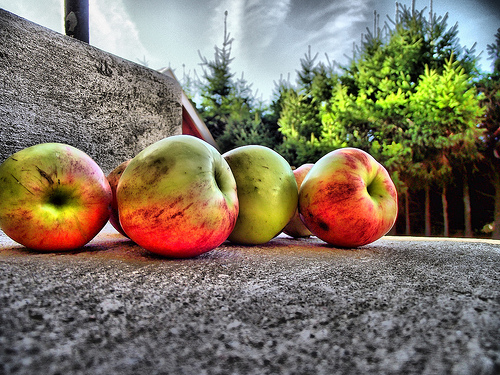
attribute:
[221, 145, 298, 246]
apple — green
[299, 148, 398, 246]
apple — red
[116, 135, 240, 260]
apple — red, green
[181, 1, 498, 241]
trees — tall, green, red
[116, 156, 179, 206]
marks — brown, black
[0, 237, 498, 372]
ground — concrete, gray, stone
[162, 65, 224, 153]
roof — red, white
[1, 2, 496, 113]
sky — cloudy, blue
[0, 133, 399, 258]
apples — red, green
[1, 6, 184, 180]
wall — gray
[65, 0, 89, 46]
pipe — black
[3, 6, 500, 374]
bench — gray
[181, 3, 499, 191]
leaves — green